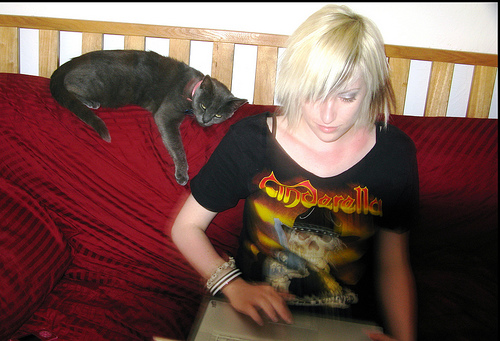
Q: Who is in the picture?
A: A woman and her cat.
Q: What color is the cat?
A: Grey.